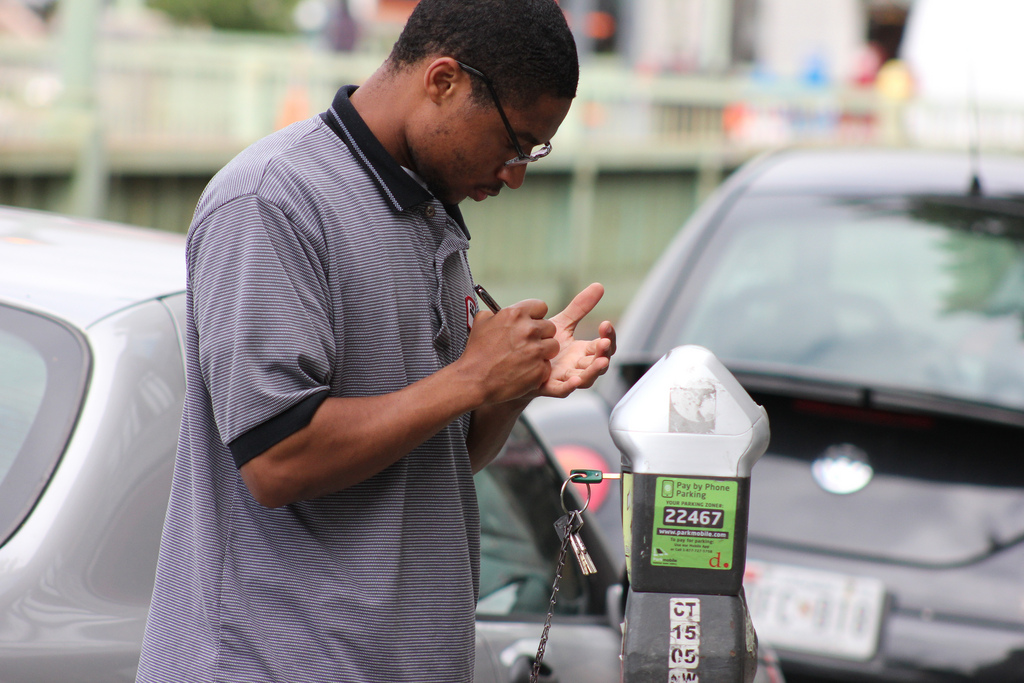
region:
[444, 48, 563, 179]
A pair of glasses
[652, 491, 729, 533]
"22467" written on sticker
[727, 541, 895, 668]
A white license plate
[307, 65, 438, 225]
A collar of a shirt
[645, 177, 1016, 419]
Back window of a car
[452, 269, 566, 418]
A pen in a hand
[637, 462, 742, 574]
A green square sticker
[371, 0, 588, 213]
Black hair on a man's head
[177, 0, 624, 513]
A man is writing on his hand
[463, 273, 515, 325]
The pen is black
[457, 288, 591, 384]
man holding a pen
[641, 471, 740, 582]
green sticker on the meter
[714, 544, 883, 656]
license plate on the car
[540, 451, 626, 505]
key on the parking meter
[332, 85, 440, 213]
black collar on the shirt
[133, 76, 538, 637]
man wearing a stripe shirt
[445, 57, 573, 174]
The white glasses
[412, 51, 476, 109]
The left ear of the man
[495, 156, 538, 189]
The nose of the man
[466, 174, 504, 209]
The mouth of the man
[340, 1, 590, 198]
The face of the man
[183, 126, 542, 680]
The shirt of the man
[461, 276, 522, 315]
The black pen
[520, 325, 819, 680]
The silver parking meter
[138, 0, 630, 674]
A man near a silver car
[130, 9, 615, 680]
Guy writing on his hand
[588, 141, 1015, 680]
Blurry black car in background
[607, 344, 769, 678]
Phone parking stand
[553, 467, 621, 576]
Keys inside the phone parking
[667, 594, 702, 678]
Symbols on the side on meter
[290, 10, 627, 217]
head of the man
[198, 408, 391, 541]
elbow of the man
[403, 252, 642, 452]
hands of the man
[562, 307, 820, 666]
meter next to man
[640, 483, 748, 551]
numbers on the meter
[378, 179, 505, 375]
buttons on the shirt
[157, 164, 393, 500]
sleeve of the shirt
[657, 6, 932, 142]
people in the distance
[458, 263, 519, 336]
pen in man's hand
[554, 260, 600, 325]
the mans thumb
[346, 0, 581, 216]
the mans head above shoulders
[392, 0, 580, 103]
the hair on the mans head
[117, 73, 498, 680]
the mans shirt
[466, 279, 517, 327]
the mans pen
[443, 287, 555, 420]
the mans hand at end of arm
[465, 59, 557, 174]
the mans glasses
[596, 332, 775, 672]
the parking meter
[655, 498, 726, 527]
the numbers on the meter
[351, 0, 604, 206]
the mans head above shoulders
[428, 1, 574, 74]
the hair on the mans head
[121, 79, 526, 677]
the mans shirt